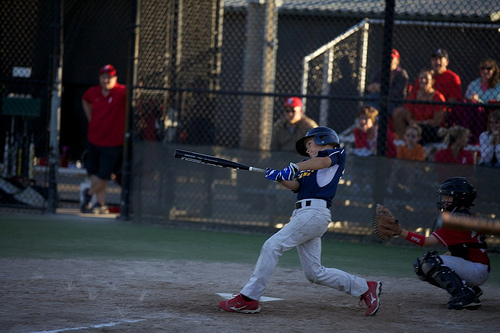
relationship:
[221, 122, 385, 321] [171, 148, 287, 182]
batter swings bat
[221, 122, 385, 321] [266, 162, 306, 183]
batter has baseball gloves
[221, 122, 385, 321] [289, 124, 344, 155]
batter wearing a helmet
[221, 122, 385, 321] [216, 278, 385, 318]
batter has red shoes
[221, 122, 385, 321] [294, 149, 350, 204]
batter wearing shirt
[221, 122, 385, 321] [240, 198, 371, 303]
batter wearing pants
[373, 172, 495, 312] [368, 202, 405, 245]
catcher has a baseball mitt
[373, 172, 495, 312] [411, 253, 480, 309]
catcher wearing protective gear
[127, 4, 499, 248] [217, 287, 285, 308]
chain link fence behind home plate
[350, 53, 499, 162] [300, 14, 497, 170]
spectators are in stands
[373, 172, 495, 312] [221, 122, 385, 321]
catcher behind batter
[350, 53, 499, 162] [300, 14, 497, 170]
spectators are watching in stands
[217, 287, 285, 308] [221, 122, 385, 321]
homeplate near batter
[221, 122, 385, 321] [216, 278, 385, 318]
batter wearing red shoes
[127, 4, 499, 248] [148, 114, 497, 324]
chain link fence behind players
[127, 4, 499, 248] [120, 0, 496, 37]
chain link fence used for covers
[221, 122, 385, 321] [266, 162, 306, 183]
batter wearing baseball gloves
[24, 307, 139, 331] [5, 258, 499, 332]
baseline painted on dirt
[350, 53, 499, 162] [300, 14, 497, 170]
spectators are sitting in stands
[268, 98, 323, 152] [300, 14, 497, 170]
spectator sitting in stands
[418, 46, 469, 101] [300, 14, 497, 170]
spectator sitting in stands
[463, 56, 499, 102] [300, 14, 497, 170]
spectator sitting in stands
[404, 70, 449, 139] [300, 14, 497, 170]
person in stands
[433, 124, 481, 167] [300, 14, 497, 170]
person in stands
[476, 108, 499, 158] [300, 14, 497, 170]
person in stands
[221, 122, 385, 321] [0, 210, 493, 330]
batter on field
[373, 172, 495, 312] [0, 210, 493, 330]
catcher on field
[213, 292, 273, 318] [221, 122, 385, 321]
shoe on batter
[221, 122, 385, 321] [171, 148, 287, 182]
batter with a bat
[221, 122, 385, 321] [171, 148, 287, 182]
batter swinging a bat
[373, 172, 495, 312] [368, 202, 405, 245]
catcher wearing baseball mitt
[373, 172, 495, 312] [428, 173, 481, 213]
catcher wearing a helmet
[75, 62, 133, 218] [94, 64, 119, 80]
man wearing cap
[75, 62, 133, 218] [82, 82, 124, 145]
man wearing a red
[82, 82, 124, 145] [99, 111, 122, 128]
red on man red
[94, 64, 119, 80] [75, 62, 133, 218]
cap red on man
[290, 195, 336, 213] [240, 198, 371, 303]
black belt on white pants